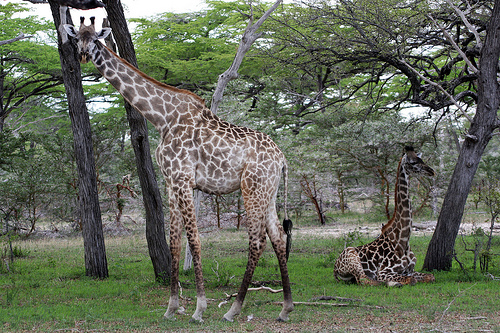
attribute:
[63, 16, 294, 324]
giraffe — standing, tall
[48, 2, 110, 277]
tree — tall, large, brown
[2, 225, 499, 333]
grass — green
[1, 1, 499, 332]
park — green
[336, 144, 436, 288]
giraffe — lying, sitting